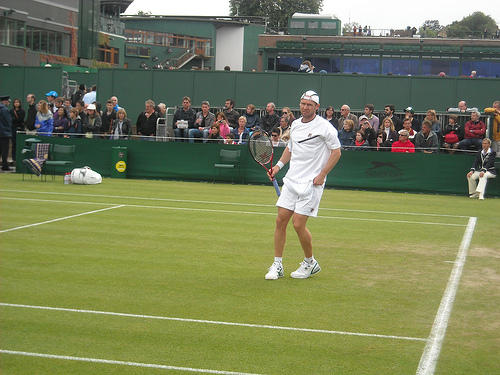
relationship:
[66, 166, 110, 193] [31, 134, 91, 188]
duffel bag next to chair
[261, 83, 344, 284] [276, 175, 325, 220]
man wearing shorts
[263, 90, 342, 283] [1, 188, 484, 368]
man on court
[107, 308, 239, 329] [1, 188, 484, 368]
line on court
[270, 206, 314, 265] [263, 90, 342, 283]
legs of man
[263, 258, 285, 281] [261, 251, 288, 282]
shoe on foot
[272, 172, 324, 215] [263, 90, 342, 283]
shorts on man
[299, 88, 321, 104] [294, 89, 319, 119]
hat on head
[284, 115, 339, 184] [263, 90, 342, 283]
shirt on man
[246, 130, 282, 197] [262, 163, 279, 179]
tennis racket in hand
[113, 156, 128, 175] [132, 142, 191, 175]
dot on fence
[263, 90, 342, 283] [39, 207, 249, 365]
man on court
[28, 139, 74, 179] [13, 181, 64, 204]
chair on ground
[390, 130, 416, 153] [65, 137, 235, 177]
man are in stands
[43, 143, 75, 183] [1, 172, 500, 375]
chair sitting on court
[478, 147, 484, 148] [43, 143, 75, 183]
woman sitting on chair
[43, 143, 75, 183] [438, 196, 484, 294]
chair on tennis court.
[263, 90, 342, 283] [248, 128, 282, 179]
man holding a tennis racket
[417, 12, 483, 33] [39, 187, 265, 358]
trees are behind tennis courts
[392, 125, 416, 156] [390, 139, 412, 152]
man has on a sweater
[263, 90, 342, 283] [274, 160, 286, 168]
man wearing a wristband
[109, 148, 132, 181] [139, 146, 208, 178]
trash can against banner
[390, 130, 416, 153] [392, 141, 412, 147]
man wearing a sweater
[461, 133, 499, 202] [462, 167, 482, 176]
woman has hands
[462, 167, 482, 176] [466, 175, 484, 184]
hands on knees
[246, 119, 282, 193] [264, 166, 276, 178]
tennis racket on hand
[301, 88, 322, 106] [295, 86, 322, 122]
scarf on head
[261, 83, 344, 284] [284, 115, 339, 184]
man wears shirt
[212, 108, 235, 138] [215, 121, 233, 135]
lady wears sweatshirt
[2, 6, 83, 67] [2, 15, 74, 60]
building has windows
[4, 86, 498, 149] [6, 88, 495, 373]
spectators watch tennis match